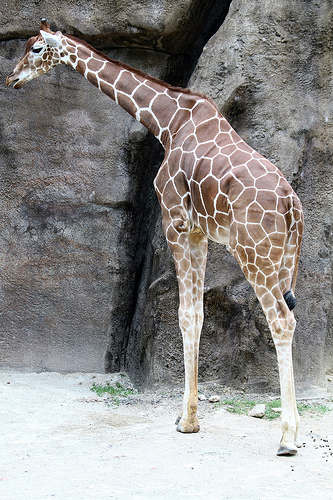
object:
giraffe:
[8, 17, 301, 458]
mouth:
[8, 76, 21, 88]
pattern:
[190, 146, 247, 220]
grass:
[102, 386, 114, 392]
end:
[283, 290, 297, 312]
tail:
[280, 194, 305, 310]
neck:
[60, 30, 192, 150]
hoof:
[278, 443, 296, 457]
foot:
[277, 417, 301, 458]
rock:
[250, 402, 266, 418]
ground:
[0, 370, 330, 499]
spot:
[191, 157, 212, 184]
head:
[6, 18, 64, 92]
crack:
[104, 1, 233, 372]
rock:
[0, 0, 330, 396]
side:
[1, 44, 144, 372]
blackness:
[156, 1, 213, 84]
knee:
[176, 308, 197, 335]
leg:
[171, 219, 197, 433]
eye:
[31, 46, 43, 53]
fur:
[60, 28, 163, 106]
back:
[198, 103, 288, 189]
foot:
[177, 387, 199, 434]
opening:
[223, 85, 252, 134]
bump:
[17, 179, 79, 219]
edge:
[125, 234, 166, 394]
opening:
[178, 221, 187, 229]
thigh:
[153, 166, 203, 240]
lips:
[7, 76, 20, 88]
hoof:
[177, 418, 198, 434]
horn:
[40, 18, 48, 31]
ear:
[37, 27, 51, 42]